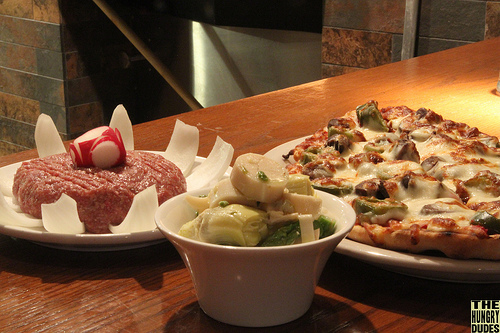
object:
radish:
[66, 126, 128, 168]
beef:
[15, 150, 188, 228]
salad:
[177, 154, 335, 246]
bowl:
[153, 189, 355, 329]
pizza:
[277, 98, 500, 254]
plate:
[256, 133, 499, 286]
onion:
[110, 184, 159, 235]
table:
[238, 80, 340, 165]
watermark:
[471, 299, 499, 333]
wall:
[7, 51, 62, 99]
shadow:
[159, 298, 218, 332]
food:
[0, 101, 500, 333]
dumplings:
[179, 204, 271, 247]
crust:
[387, 220, 458, 255]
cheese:
[402, 191, 428, 208]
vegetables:
[256, 218, 300, 247]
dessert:
[15, 153, 186, 230]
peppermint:
[114, 187, 130, 197]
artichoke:
[268, 210, 299, 236]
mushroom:
[420, 155, 445, 172]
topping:
[356, 99, 389, 132]